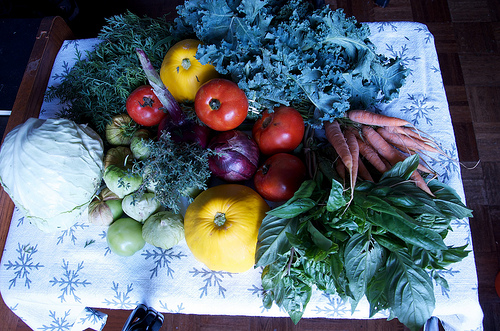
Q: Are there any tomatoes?
A: Yes, there is a tomato.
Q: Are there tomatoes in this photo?
A: Yes, there is a tomato.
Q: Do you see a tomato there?
A: Yes, there is a tomato.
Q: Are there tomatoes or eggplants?
A: Yes, there is a tomato.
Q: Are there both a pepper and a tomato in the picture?
A: No, there is a tomato but no peppers.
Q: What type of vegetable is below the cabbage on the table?
A: The vegetable is a tomato.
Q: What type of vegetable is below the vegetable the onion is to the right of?
A: The vegetable is a tomato.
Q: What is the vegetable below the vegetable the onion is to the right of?
A: The vegetable is a tomato.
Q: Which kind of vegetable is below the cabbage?
A: The vegetable is a tomato.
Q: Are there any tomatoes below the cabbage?
A: Yes, there is a tomato below the cabbage.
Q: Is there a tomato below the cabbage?
A: Yes, there is a tomato below the cabbage.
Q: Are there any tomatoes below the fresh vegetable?
A: Yes, there is a tomato below the cabbage.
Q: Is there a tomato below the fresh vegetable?
A: Yes, there is a tomato below the cabbage.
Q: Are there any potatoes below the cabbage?
A: No, there is a tomato below the cabbage.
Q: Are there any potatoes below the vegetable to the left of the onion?
A: No, there is a tomato below the cabbage.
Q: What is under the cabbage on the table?
A: The tomato is under the cabbage.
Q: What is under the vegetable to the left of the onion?
A: The tomato is under the cabbage.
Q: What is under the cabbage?
A: The tomato is under the cabbage.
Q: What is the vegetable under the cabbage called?
A: The vegetable is a tomato.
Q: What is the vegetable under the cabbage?
A: The vegetable is a tomato.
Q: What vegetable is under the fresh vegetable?
A: The vegetable is a tomato.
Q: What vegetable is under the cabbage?
A: The vegetable is a tomato.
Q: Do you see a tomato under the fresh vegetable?
A: Yes, there is a tomato under the cabbage.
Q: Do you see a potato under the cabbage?
A: No, there is a tomato under the cabbage.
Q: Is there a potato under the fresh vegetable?
A: No, there is a tomato under the cabbage.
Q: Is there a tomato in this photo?
A: Yes, there are tomatoes.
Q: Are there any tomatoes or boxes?
A: Yes, there are tomatoes.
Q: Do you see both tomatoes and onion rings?
A: No, there are tomatoes but no onion rings.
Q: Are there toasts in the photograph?
A: No, there are no toasts.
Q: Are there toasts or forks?
A: No, there are no toasts or forks.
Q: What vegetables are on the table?
A: The vegetables are tomatoes.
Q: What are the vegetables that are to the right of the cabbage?
A: The vegetables are tomatoes.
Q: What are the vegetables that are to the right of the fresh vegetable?
A: The vegetables are tomatoes.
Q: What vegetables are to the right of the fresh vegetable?
A: The vegetables are tomatoes.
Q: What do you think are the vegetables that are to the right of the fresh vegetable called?
A: The vegetables are tomatoes.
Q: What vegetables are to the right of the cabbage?
A: The vegetables are tomatoes.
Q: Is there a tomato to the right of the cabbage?
A: Yes, there are tomatoes to the right of the cabbage.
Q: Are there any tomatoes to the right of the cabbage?
A: Yes, there are tomatoes to the right of the cabbage.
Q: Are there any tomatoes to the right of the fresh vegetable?
A: Yes, there are tomatoes to the right of the cabbage.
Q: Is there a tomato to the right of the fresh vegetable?
A: Yes, there are tomatoes to the right of the cabbage.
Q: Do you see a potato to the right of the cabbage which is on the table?
A: No, there are tomatoes to the right of the cabbage.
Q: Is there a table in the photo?
A: Yes, there is a table.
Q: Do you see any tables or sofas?
A: Yes, there is a table.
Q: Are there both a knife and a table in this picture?
A: No, there is a table but no knives.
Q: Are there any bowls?
A: No, there are no bowls.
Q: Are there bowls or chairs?
A: No, there are no bowls or chairs.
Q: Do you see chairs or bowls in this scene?
A: No, there are no bowls or chairs.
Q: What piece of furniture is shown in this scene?
A: The piece of furniture is a table.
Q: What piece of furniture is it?
A: The piece of furniture is a table.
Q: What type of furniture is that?
A: This is a table.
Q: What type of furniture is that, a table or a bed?
A: This is a table.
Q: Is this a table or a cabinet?
A: This is a table.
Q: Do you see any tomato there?
A: Yes, there is a tomato.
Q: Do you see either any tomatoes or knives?
A: Yes, there is a tomato.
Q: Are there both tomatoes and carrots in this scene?
A: Yes, there are both a tomato and carrots.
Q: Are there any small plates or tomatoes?
A: Yes, there is a small tomato.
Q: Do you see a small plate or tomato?
A: Yes, there is a small tomato.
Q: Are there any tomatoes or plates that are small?
A: Yes, the tomato is small.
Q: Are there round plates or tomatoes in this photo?
A: Yes, there is a round tomato.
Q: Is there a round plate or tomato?
A: Yes, there is a round tomato.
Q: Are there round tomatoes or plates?
A: Yes, there is a round tomato.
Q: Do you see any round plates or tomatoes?
A: Yes, there is a round tomato.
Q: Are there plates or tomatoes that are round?
A: Yes, the tomato is round.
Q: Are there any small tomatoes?
A: Yes, there is a small tomato.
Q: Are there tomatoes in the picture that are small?
A: Yes, there is a tomato that is small.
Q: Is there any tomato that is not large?
A: Yes, there is a small tomato.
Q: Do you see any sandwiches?
A: No, there are no sandwiches.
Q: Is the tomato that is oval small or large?
A: The tomato is small.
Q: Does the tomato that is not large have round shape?
A: Yes, the tomato is round.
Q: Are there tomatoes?
A: Yes, there is a tomato.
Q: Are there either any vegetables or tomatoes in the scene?
A: Yes, there is a tomato.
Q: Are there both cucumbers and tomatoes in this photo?
A: No, there is a tomato but no cucumbers.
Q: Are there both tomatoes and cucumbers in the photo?
A: No, there is a tomato but no cucumbers.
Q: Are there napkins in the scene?
A: No, there are no napkins.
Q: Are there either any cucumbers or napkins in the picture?
A: No, there are no napkins or cucumbers.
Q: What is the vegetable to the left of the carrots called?
A: The vegetable is a tomato.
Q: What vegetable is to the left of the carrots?
A: The vegetable is a tomato.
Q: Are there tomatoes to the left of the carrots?
A: Yes, there is a tomato to the left of the carrots.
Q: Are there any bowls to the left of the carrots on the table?
A: No, there is a tomato to the left of the carrots.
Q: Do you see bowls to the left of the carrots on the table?
A: No, there is a tomato to the left of the carrots.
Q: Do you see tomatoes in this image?
A: Yes, there is a tomato.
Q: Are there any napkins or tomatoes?
A: Yes, there is a tomato.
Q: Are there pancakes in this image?
A: No, there are no pancakes.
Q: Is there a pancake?
A: No, there are no pancakes.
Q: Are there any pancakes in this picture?
A: No, there are no pancakes.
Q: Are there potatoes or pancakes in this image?
A: No, there are no pancakes or potatoes.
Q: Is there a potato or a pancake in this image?
A: No, there are no pancakes or potatoes.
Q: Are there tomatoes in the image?
A: Yes, there is a tomato.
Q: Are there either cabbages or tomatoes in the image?
A: Yes, there is a tomato.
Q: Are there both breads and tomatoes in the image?
A: No, there is a tomato but no breads.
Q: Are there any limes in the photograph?
A: No, there are no limes.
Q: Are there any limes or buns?
A: No, there are no limes or buns.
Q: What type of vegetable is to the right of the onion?
A: The vegetable is a tomato.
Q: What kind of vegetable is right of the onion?
A: The vegetable is a tomato.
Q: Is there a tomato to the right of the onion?
A: Yes, there is a tomato to the right of the onion.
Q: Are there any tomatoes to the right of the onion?
A: Yes, there is a tomato to the right of the onion.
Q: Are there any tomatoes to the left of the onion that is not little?
A: No, the tomato is to the right of the onion.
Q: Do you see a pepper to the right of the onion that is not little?
A: No, there is a tomato to the right of the onion.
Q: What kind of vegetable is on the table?
A: The vegetable is a squash.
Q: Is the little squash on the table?
A: Yes, the squash is on the table.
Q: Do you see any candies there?
A: No, there are no candies.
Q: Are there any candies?
A: No, there are no candies.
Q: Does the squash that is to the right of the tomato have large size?
A: Yes, the squash is large.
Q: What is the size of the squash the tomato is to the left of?
A: The squash is large.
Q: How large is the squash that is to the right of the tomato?
A: The squash is large.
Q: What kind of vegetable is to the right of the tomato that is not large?
A: The vegetable is a squash.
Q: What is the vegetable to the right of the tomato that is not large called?
A: The vegetable is a squash.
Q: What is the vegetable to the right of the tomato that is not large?
A: The vegetable is a squash.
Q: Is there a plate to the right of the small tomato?
A: No, there is a squash to the right of the tomato.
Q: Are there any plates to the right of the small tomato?
A: No, there is a squash to the right of the tomato.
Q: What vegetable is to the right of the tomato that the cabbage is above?
A: The vegetable is a squash.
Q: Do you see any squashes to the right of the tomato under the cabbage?
A: Yes, there is a squash to the right of the tomato.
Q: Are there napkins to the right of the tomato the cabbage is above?
A: No, there is a squash to the right of the tomato.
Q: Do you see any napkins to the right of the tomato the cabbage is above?
A: No, there is a squash to the right of the tomato.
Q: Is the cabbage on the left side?
A: Yes, the cabbage is on the left of the image.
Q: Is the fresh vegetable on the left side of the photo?
A: Yes, the cabbage is on the left of the image.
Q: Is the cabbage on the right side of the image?
A: No, the cabbage is on the left of the image.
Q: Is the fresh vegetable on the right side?
A: No, the cabbage is on the left of the image.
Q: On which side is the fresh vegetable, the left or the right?
A: The cabbage is on the left of the image.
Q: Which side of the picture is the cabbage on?
A: The cabbage is on the left of the image.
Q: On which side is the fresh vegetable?
A: The cabbage is on the left of the image.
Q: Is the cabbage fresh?
A: Yes, the cabbage is fresh.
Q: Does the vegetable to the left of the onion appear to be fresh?
A: Yes, the cabbage is fresh.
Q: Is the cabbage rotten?
A: No, the cabbage is fresh.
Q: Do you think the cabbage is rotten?
A: No, the cabbage is fresh.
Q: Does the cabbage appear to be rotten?
A: No, the cabbage is fresh.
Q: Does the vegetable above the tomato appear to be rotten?
A: No, the cabbage is fresh.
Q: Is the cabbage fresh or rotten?
A: The cabbage is fresh.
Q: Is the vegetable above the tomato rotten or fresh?
A: The cabbage is fresh.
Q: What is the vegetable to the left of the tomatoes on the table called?
A: The vegetable is a cabbage.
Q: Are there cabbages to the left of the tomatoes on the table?
A: Yes, there is a cabbage to the left of the tomatoes.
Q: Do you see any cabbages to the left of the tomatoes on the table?
A: Yes, there is a cabbage to the left of the tomatoes.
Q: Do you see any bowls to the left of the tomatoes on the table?
A: No, there is a cabbage to the left of the tomatoes.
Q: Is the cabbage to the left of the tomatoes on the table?
A: Yes, the cabbage is to the left of the tomatoes.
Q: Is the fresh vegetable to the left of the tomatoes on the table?
A: Yes, the cabbage is to the left of the tomatoes.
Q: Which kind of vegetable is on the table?
A: The vegetable is a cabbage.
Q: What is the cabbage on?
A: The cabbage is on the table.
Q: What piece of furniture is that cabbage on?
A: The cabbage is on the table.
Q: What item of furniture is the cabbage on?
A: The cabbage is on the table.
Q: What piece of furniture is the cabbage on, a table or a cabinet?
A: The cabbage is on a table.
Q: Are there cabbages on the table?
A: Yes, there is a cabbage on the table.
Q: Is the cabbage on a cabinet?
A: No, the cabbage is on the table.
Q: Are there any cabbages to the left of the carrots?
A: Yes, there is a cabbage to the left of the carrots.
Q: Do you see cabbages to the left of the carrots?
A: Yes, there is a cabbage to the left of the carrots.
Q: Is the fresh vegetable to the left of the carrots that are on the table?
A: Yes, the cabbage is to the left of the carrots.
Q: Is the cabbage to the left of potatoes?
A: No, the cabbage is to the left of the carrots.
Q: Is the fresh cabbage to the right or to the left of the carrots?
A: The cabbage is to the left of the carrots.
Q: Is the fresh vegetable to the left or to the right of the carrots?
A: The cabbage is to the left of the carrots.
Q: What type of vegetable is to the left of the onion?
A: The vegetable is a cabbage.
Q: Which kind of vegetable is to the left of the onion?
A: The vegetable is a cabbage.